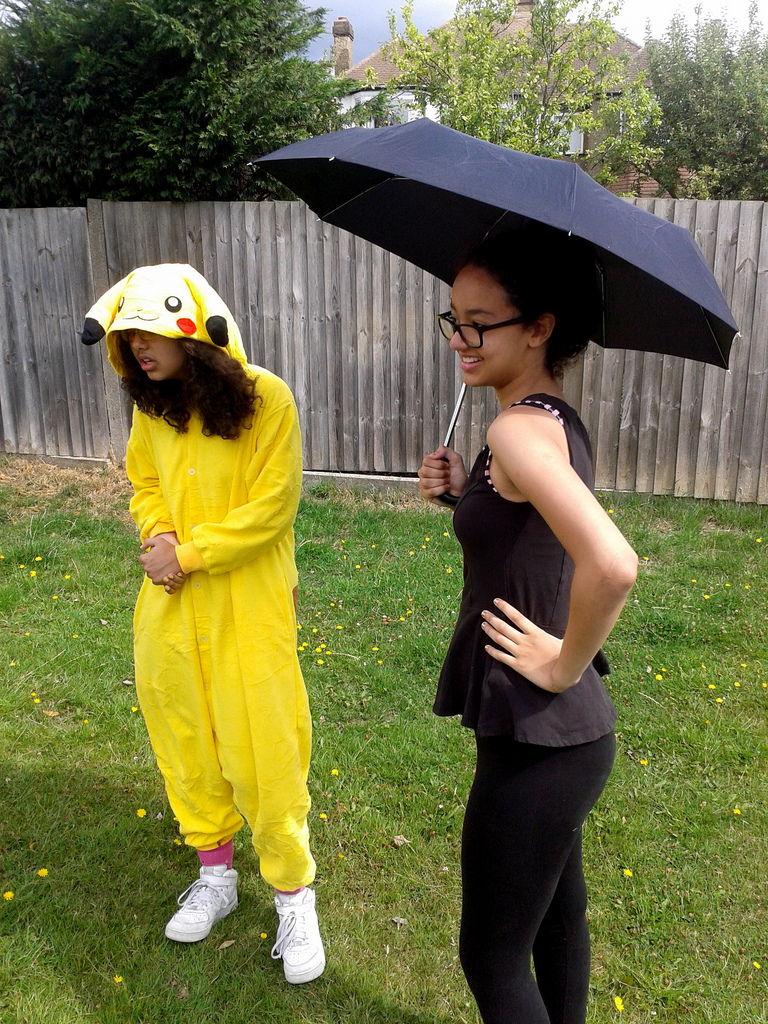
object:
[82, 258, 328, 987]
adult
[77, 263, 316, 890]
pjs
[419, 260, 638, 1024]
girl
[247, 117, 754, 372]
umbrella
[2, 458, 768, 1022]
grass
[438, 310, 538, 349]
glasses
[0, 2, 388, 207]
tree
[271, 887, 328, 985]
shoes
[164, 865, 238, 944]
shoes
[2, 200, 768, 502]
fence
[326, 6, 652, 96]
roof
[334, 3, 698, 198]
house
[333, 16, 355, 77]
chimney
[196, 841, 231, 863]
socks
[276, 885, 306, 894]
socks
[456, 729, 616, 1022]
tights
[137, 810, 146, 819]
flowers